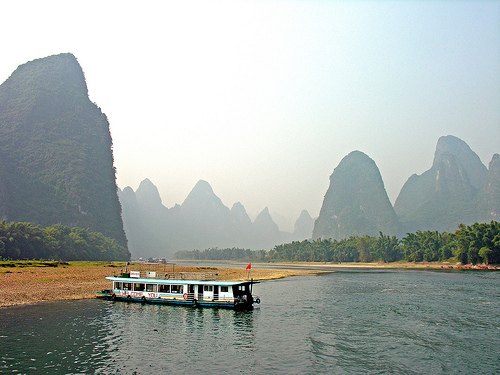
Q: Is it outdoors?
A: Yes, it is outdoors.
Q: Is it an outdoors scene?
A: Yes, it is outdoors.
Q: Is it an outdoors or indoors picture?
A: It is outdoors.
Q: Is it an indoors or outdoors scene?
A: It is outdoors.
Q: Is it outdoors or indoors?
A: It is outdoors.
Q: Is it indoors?
A: No, it is outdoors.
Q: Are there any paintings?
A: No, there are no paintings.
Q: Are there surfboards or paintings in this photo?
A: No, there are no paintings or surfboards.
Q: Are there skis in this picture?
A: No, there are no skis.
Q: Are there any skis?
A: No, there are no skis.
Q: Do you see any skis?
A: No, there are no skis.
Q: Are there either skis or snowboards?
A: No, there are no skis or snowboards.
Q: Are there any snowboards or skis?
A: No, there are no skis or snowboards.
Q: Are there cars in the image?
A: No, there are no cars.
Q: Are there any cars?
A: No, there are no cars.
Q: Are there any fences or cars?
A: No, there are no cars or fences.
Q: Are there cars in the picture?
A: No, there are no cars.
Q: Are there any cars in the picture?
A: No, there are no cars.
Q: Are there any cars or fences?
A: No, there are no cars or fences.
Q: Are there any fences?
A: No, there are no fences.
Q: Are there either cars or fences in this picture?
A: No, there are no fences or cars.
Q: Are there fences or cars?
A: No, there are no fences or cars.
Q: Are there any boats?
A: Yes, there is a boat.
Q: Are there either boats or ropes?
A: Yes, there is a boat.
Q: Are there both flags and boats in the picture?
A: Yes, there are both a boat and a flag.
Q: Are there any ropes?
A: No, there are no ropes.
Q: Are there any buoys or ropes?
A: No, there are no ropes or buoys.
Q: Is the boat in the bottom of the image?
A: Yes, the boat is in the bottom of the image.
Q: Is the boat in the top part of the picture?
A: No, the boat is in the bottom of the image.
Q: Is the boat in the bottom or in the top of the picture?
A: The boat is in the bottom of the image.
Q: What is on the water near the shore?
A: The boat is on the water.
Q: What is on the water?
A: The boat is on the water.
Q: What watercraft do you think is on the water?
A: The watercraft is a boat.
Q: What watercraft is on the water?
A: The watercraft is a boat.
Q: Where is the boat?
A: The boat is on the water.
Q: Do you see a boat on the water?
A: Yes, there is a boat on the water.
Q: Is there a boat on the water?
A: Yes, there is a boat on the water.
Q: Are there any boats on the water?
A: Yes, there is a boat on the water.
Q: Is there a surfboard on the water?
A: No, there is a boat on the water.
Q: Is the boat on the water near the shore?
A: Yes, the boat is on the water.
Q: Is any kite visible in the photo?
A: No, there are no kites.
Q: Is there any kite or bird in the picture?
A: No, there are no kites or birds.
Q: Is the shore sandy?
A: Yes, the shore is sandy.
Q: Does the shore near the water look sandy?
A: Yes, the shore is sandy.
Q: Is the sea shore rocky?
A: No, the sea shore is sandy.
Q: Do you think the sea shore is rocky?
A: No, the sea shore is sandy.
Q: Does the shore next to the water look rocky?
A: No, the shore is sandy.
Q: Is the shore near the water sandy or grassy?
A: The shore is sandy.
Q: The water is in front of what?
A: The water is in front of the tree.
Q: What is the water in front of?
A: The water is in front of the tree.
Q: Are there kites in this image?
A: No, there are no kites.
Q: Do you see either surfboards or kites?
A: No, there are no kites or surfboards.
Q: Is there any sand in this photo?
A: Yes, there is sand.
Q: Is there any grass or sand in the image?
A: Yes, there is sand.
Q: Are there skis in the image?
A: No, there are no skis.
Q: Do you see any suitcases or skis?
A: No, there are no skis or suitcases.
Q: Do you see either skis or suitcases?
A: No, there are no skis or suitcases.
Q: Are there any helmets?
A: No, there are no helmets.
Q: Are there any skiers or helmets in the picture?
A: No, there are no helmets or skiers.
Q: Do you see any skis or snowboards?
A: No, there are no skis or snowboards.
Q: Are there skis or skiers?
A: No, there are no skis or skiers.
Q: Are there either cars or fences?
A: No, there are no cars or fences.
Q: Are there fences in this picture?
A: No, there are no fences.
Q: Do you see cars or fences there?
A: No, there are no fences or cars.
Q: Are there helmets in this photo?
A: No, there are no helmets.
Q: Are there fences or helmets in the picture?
A: No, there are no helmets or fences.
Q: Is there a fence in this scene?
A: No, there are no fences.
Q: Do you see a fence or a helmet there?
A: No, there are no fences or helmets.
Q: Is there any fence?
A: No, there are no fences.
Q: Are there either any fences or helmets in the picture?
A: No, there are no fences or helmets.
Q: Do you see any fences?
A: No, there are no fences.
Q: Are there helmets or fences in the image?
A: No, there are no fences or helmets.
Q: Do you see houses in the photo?
A: No, there are no houses.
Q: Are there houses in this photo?
A: No, there are no houses.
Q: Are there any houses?
A: No, there are no houses.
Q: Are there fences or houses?
A: No, there are no houses or fences.